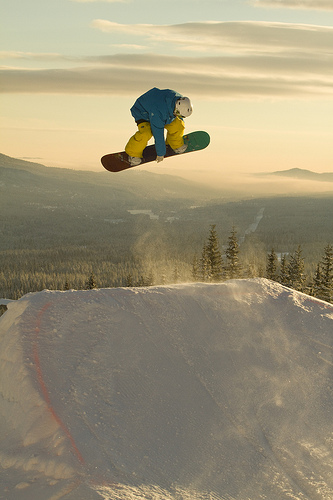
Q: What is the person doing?
A: Snowboarding.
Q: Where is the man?
A: In the air.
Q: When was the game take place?
A: Daytime.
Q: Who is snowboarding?
A: A person.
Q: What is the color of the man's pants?
A: Yellow.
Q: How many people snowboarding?
A: One.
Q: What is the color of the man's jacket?
A: Blue.